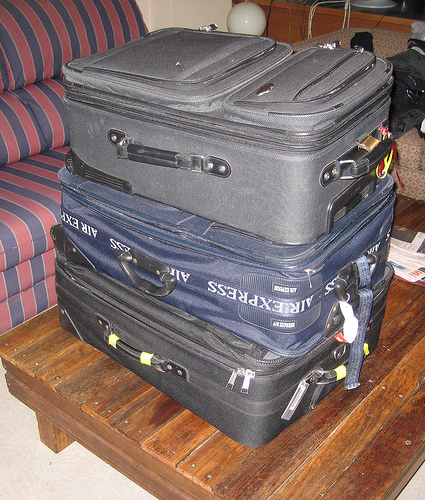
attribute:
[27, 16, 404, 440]
suitcase — stacked, colored, blue, stack, black, grey, gray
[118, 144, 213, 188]
handle — plastic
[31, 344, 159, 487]
table — wood, wooden, coffee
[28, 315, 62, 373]
line — red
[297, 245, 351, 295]
zipper — metal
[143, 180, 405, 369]
bag — black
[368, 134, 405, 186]
word — yellow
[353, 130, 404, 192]
tag — yellow, white, red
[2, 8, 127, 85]
couch — red, pink, stripped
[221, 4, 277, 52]
light — round, white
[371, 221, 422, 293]
newspaper — laying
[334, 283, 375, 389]
strap — blue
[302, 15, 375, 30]
chord — hanging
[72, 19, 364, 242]
luggage — grey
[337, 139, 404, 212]
tape — yellow